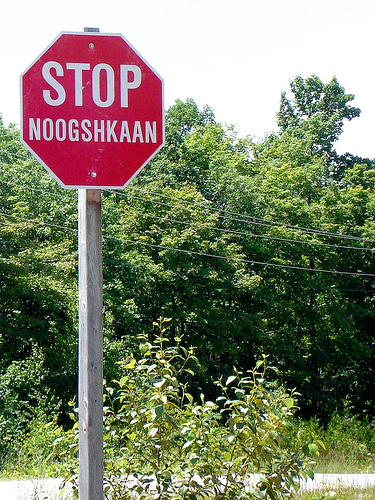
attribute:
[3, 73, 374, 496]
leaves — green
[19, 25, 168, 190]
board — sign, attached, red, white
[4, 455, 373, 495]
road — grey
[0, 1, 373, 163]
sky — white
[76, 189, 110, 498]
pole — gray, wooden, sign, wood, sign's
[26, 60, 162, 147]
letters — white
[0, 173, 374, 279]
lines — wire, passing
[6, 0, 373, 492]
picture — daytime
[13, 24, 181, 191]
sign — mounted, stop, white, red, traffic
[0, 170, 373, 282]
wires — hanging, electrical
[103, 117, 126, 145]
letter — k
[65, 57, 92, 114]
letter — t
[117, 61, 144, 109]
letter — p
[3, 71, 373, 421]
trees — green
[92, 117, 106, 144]
letter — h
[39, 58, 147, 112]
stop — word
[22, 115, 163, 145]
word — noogshkaan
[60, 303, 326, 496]
bush — gren, growing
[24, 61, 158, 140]
language — english, foreign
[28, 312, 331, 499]
weeds — growing